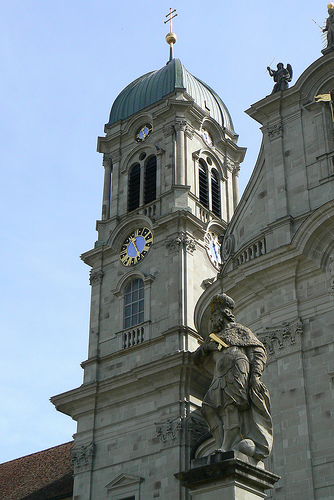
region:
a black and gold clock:
[111, 227, 160, 264]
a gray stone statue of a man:
[204, 295, 271, 461]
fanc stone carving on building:
[149, 412, 181, 443]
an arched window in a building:
[121, 276, 149, 322]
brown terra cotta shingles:
[6, 452, 59, 487]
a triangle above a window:
[102, 470, 144, 487]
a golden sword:
[209, 332, 226, 349]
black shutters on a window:
[198, 172, 218, 204]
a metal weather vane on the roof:
[153, 3, 183, 56]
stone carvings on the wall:
[268, 315, 310, 349]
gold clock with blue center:
[117, 225, 155, 264]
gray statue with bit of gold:
[189, 290, 274, 473]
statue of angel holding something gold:
[264, 56, 297, 97]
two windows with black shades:
[122, 141, 166, 211]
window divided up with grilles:
[103, 268, 164, 347]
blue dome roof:
[106, 46, 235, 131]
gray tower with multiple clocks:
[49, 4, 221, 499]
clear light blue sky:
[0, 0, 330, 463]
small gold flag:
[309, 87, 328, 109]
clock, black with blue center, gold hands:
[129, 117, 154, 141]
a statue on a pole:
[173, 270, 303, 498]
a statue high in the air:
[167, 272, 332, 477]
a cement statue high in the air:
[155, 279, 288, 496]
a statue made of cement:
[138, 273, 302, 498]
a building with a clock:
[67, 31, 263, 386]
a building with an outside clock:
[48, 51, 298, 437]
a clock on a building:
[70, 49, 274, 378]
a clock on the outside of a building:
[34, 53, 217, 327]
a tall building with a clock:
[61, 53, 214, 330]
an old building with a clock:
[72, 96, 296, 369]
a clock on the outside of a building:
[21, 106, 319, 400]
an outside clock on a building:
[88, 94, 243, 313]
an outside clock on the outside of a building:
[92, 150, 274, 361]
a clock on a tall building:
[62, 36, 278, 390]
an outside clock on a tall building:
[42, 47, 284, 432]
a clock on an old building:
[63, 87, 314, 381]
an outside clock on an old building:
[43, 79, 287, 387]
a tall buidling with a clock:
[66, 75, 238, 379]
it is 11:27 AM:
[115, 224, 154, 268]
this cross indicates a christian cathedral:
[158, 4, 181, 65]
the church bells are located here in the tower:
[95, 130, 241, 234]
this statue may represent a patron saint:
[192, 291, 281, 480]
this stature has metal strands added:
[311, 2, 332, 57]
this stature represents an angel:
[261, 56, 294, 99]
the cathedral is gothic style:
[45, 4, 333, 498]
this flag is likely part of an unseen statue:
[310, 88, 332, 127]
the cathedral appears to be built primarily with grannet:
[69, 3, 331, 499]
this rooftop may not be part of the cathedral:
[0, 435, 86, 498]